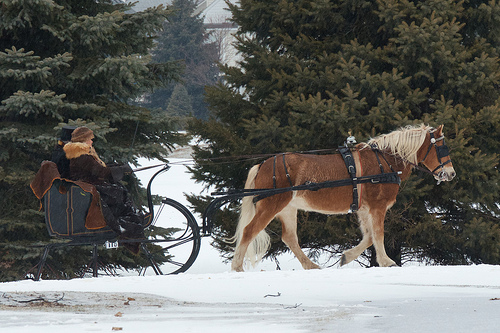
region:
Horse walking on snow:
[228, 246, 423, 277]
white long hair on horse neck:
[381, 125, 423, 152]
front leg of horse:
[355, 205, 390, 270]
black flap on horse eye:
[432, 141, 447, 156]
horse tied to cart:
[30, 175, 245, 275]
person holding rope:
[115, 150, 255, 175]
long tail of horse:
[240, 165, 260, 256]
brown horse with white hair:
[245, 125, 455, 270]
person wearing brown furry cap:
[70, 126, 92, 137]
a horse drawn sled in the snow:
[25, 115, 462, 283]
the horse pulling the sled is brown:
[224, 117, 461, 275]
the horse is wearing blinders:
[433, 140, 452, 161]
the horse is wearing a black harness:
[207, 125, 407, 207]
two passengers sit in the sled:
[47, 126, 142, 224]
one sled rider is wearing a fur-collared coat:
[62, 126, 112, 183]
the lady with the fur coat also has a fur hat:
[67, 123, 98, 142]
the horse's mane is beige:
[363, 113, 437, 172]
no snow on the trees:
[213, 0, 497, 128]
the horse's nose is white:
[431, 161, 457, 182]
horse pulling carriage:
[25, 90, 462, 286]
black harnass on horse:
[165, 135, 450, 204]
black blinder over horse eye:
[433, 139, 454, 164]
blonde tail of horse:
[233, 157, 275, 265]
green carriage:
[19, 160, 205, 279]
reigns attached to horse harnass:
[123, 141, 349, 179]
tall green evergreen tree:
[185, 0, 498, 268]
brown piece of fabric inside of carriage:
[26, 155, 113, 235]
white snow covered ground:
[1, 259, 498, 331]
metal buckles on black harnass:
[341, 151, 367, 208]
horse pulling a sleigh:
[11, 100, 498, 262]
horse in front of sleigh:
[214, 113, 455, 256]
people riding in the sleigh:
[48, 122, 123, 204]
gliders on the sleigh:
[19, 193, 209, 275]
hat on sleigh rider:
[71, 124, 98, 136]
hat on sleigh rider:
[54, 121, 71, 136]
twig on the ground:
[13, 290, 75, 312]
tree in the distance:
[133, 5, 238, 125]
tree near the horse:
[202, 8, 497, 255]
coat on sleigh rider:
[66, 143, 113, 193]